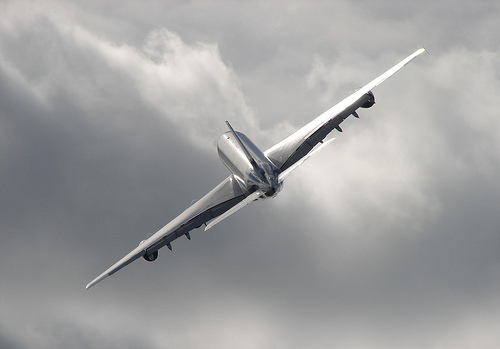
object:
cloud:
[0, 1, 500, 349]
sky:
[300, 192, 432, 287]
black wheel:
[363, 90, 376, 109]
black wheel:
[144, 249, 159, 262]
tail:
[213, 110, 291, 206]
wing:
[202, 191, 254, 237]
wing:
[83, 168, 262, 309]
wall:
[161, 194, 298, 241]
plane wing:
[82, 178, 239, 296]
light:
[271, 45, 427, 155]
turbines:
[356, 88, 374, 110]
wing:
[295, 56, 455, 171]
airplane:
[84, 46, 428, 290]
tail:
[248, 162, 283, 193]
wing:
[261, 45, 426, 168]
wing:
[83, 173, 240, 288]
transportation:
[81, 46, 426, 292]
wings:
[78, 45, 423, 290]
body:
[216, 129, 276, 196]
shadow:
[213, 144, 244, 179]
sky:
[11, 15, 328, 92]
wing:
[52, 171, 256, 311]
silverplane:
[41, 34, 463, 296]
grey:
[42, 159, 128, 219]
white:
[174, 56, 217, 103]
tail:
[225, 121, 268, 182]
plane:
[82, 40, 425, 290]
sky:
[0, 0, 498, 347]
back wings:
[223, 119, 265, 174]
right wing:
[265, 49, 428, 166]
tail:
[204, 125, 330, 238]